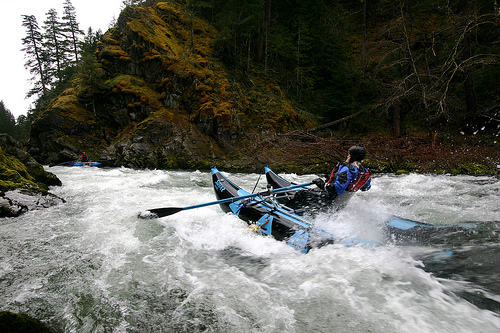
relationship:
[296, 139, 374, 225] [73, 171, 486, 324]
person in river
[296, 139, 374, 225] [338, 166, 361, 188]
person wearing shirt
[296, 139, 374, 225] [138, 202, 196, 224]
person has paddle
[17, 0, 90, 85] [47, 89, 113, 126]
tree on hill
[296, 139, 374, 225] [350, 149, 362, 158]
person has helmet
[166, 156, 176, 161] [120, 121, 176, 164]
moss on rock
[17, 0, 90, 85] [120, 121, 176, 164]
tree on rock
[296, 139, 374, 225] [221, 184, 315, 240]
person on raft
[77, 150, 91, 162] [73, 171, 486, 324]
person in river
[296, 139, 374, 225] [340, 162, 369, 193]
person has jacket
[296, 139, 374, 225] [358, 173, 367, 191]
person has backpack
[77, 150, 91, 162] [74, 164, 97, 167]
person in raft